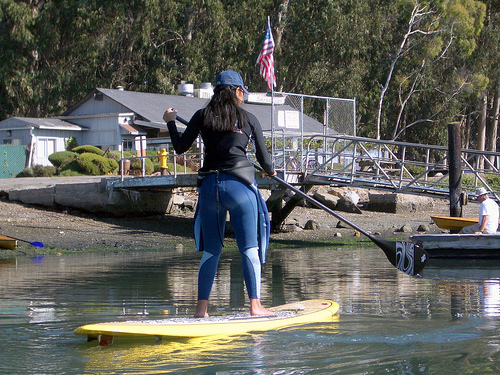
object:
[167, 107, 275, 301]
stick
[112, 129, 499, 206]
bridge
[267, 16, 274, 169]
flag pole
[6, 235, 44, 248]
oar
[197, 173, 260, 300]
blue wetsuit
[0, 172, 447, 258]
ground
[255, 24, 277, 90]
flag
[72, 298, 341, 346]
paddle board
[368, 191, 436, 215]
boulder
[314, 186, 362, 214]
boulder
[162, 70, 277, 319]
lady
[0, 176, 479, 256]
dock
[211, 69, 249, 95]
blue cap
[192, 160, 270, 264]
wet suit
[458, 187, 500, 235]
man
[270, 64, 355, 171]
fence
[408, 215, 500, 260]
boat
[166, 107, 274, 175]
shirt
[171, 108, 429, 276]
oar